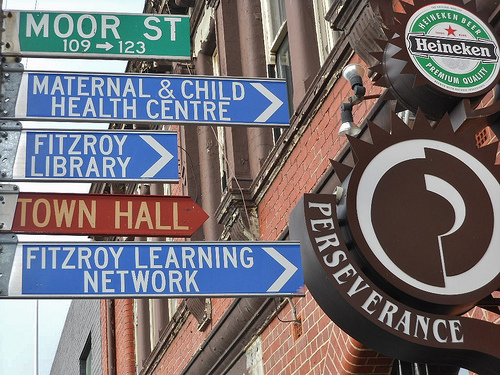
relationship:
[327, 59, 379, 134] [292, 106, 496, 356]
spot light between sign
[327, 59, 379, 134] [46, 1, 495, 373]
spot light between building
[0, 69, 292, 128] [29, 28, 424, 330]
sign says center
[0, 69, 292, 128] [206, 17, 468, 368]
sign directing to right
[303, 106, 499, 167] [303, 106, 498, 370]
spikes on sign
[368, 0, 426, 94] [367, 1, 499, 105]
spikes on sign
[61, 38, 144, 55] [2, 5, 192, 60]
numbers on sign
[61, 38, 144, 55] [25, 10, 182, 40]
numbers on moor street